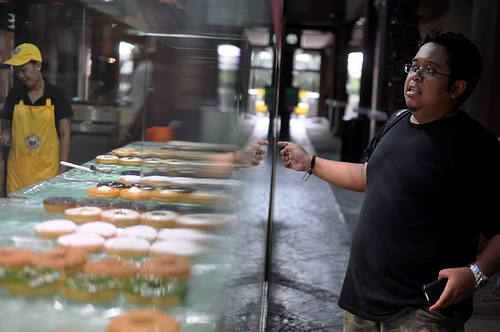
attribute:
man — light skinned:
[284, 22, 477, 314]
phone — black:
[415, 261, 450, 330]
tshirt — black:
[331, 80, 488, 299]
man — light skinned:
[300, 44, 481, 285]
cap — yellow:
[12, 34, 52, 84]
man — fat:
[338, 37, 476, 330]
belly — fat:
[328, 102, 471, 327]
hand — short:
[255, 90, 309, 193]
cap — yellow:
[5, 22, 86, 73]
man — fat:
[323, 36, 482, 316]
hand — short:
[256, 120, 332, 170]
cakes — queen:
[38, 196, 206, 275]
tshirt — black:
[334, 115, 481, 317]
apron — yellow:
[10, 100, 60, 181]